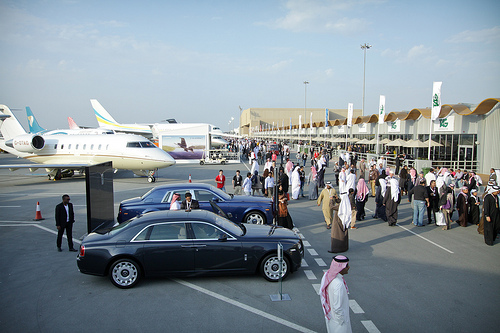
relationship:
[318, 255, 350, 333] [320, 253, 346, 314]
person wearing head covering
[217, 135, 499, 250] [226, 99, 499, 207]
people in front of building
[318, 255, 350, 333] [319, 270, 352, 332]
person wearing clothes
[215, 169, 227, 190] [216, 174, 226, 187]
person wearing shirt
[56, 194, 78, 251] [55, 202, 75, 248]
person wearing suit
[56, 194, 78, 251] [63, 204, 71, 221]
person wearing shirt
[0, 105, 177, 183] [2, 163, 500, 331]
plane parked on ground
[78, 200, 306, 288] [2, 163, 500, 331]
car parked on ground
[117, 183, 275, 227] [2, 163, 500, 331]
car parked on ground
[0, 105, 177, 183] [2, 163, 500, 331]
plane on top of ground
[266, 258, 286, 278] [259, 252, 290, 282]
rims on tire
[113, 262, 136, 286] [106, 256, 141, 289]
rims on tire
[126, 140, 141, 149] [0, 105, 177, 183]
window on front of plane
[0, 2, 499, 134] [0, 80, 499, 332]
sky above airport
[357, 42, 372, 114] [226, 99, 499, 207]
light pole above building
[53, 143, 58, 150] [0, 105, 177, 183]
window on side of plane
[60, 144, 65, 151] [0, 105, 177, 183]
window on side of plane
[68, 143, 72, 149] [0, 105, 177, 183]
window on side of plane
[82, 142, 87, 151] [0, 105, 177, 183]
window on side of plane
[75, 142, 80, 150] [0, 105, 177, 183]
window on side of plane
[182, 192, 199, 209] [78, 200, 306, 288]
person standing behind car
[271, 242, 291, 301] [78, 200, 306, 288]
sign next to car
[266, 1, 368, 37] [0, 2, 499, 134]
cloud floating in sky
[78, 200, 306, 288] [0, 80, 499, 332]
car parked at airport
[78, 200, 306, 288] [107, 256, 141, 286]
car has back right wheel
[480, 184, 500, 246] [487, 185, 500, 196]
person wearing scarf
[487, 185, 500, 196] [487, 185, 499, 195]
scarf around head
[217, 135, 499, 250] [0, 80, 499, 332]
people at airport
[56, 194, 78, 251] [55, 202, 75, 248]
man wearing suit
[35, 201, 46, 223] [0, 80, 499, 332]
traffic cone at airport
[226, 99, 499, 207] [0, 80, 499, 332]
building at airport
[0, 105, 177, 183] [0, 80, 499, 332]
plane at airport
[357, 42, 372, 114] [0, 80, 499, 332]
light pole at airport